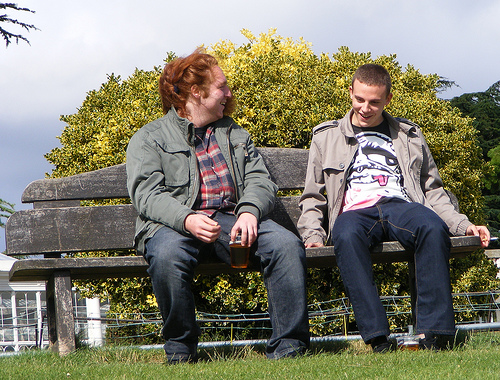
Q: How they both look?
A: Happy.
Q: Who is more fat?
A: Long hair person.